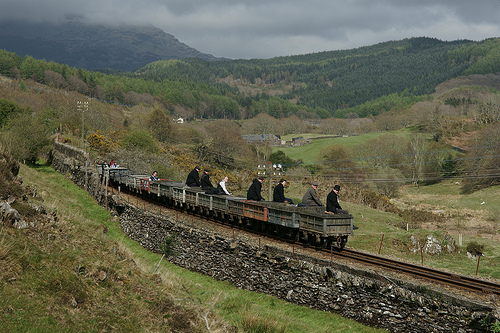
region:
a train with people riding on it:
[3, 140, 363, 255]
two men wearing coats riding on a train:
[302, 176, 351, 249]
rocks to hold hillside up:
[114, 210, 438, 331]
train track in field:
[343, 234, 495, 297]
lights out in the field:
[223, 159, 306, 174]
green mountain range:
[7, 35, 499, 110]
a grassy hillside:
[345, 36, 497, 105]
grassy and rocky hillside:
[6, 243, 222, 327]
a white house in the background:
[143, 109, 207, 130]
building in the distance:
[236, 122, 366, 149]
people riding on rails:
[191, 151, 398, 269]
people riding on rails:
[101, 100, 346, 278]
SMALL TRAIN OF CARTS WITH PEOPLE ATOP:
[77, 146, 363, 236]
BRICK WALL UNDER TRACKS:
[146, 226, 363, 330]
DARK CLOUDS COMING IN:
[5, 10, 495, 42]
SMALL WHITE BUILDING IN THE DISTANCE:
[163, 113, 185, 128]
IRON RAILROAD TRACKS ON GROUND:
[358, 247, 498, 304]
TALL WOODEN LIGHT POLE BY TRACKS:
[68, 84, 90, 159]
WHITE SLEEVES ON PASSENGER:
[213, 173, 240, 203]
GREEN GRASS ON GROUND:
[171, 284, 367, 323]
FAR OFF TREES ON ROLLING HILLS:
[174, 52, 459, 140]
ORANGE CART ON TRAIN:
[238, 187, 276, 224]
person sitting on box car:
[326, 180, 352, 220]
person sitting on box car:
[308, 180, 323, 209]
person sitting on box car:
[273, 174, 293, 204]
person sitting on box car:
[247, 169, 264, 201]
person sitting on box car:
[218, 173, 230, 195]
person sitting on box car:
[195, 170, 212, 189]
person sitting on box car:
[186, 165, 205, 189]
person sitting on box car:
[148, 169, 160, 181]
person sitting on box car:
[108, 162, 122, 170]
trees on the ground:
[332, 59, 394, 99]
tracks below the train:
[353, 244, 407, 289]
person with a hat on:
[326, 179, 362, 206]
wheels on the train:
[265, 222, 332, 259]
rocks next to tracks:
[252, 253, 307, 298]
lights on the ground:
[61, 88, 118, 126]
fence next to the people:
[371, 225, 430, 258]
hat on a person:
[328, 179, 349, 197]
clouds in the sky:
[230, 11, 284, 45]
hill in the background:
[108, 8, 187, 65]